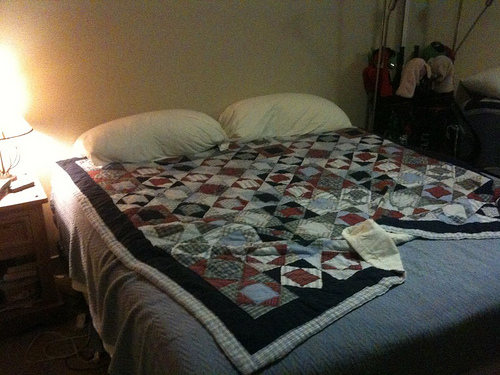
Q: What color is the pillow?
A: White.